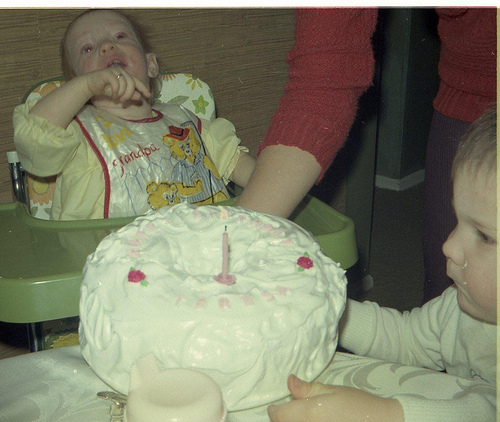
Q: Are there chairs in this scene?
A: Yes, there is a chair.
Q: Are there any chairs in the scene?
A: Yes, there is a chair.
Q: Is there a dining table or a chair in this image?
A: Yes, there is a chair.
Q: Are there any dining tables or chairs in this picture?
A: Yes, there is a chair.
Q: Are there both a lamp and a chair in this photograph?
A: No, there is a chair but no lamps.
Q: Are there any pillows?
A: No, there are no pillows.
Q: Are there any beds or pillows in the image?
A: No, there are no pillows or beds.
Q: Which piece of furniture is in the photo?
A: The piece of furniture is a chair.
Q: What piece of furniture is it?
A: The piece of furniture is a chair.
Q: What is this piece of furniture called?
A: This is a chair.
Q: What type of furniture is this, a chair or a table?
A: This is a chair.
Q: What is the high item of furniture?
A: The piece of furniture is a chair.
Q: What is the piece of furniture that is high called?
A: The piece of furniture is a chair.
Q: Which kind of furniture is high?
A: The furniture is a chair.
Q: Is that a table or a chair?
A: That is a chair.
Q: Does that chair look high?
A: Yes, the chair is high.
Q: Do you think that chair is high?
A: Yes, the chair is high.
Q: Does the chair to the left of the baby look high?
A: Yes, the chair is high.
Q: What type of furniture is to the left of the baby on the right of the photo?
A: The piece of furniture is a chair.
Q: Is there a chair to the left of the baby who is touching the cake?
A: Yes, there is a chair to the left of the baby.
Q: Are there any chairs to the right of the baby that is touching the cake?
A: No, the chair is to the left of the baby.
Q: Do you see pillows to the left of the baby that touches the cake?
A: No, there is a chair to the left of the baby.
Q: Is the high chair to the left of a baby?
A: Yes, the chair is to the left of a baby.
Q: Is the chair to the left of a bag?
A: No, the chair is to the left of a baby.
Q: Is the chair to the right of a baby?
A: No, the chair is to the left of a baby.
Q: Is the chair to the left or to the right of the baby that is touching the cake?
A: The chair is to the left of the baby.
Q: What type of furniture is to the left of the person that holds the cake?
A: The piece of furniture is a chair.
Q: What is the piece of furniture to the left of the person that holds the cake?
A: The piece of furniture is a chair.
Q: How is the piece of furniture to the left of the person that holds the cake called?
A: The piece of furniture is a chair.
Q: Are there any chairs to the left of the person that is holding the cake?
A: Yes, there is a chair to the left of the person.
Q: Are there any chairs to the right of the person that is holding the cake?
A: No, the chair is to the left of the person.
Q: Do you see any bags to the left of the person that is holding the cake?
A: No, there is a chair to the left of the person.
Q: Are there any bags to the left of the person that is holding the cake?
A: No, there is a chair to the left of the person.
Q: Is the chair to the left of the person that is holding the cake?
A: Yes, the chair is to the left of the person.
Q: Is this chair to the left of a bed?
A: No, the chair is to the left of the person.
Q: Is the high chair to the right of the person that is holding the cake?
A: No, the chair is to the left of the person.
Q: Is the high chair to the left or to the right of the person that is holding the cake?
A: The chair is to the left of the person.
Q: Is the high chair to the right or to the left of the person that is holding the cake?
A: The chair is to the left of the person.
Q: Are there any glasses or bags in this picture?
A: No, there are no glasses or bags.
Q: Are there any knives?
A: No, there are no knives.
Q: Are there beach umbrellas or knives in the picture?
A: No, there are no knives or beach umbrellas.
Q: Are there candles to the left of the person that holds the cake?
A: Yes, there is a candle to the left of the person.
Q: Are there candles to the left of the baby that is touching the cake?
A: Yes, there is a candle to the left of the baby.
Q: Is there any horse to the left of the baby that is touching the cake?
A: No, there is a candle to the left of the baby.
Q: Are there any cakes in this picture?
A: Yes, there is a cake.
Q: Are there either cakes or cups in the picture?
A: Yes, there is a cake.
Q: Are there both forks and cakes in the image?
A: No, there is a cake but no forks.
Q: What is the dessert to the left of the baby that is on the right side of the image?
A: The dessert is a cake.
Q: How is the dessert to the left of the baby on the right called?
A: The dessert is a cake.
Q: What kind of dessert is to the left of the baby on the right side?
A: The dessert is a cake.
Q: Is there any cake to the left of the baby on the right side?
A: Yes, there is a cake to the left of the baby.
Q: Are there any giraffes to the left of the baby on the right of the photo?
A: No, there is a cake to the left of the baby.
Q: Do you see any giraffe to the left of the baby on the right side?
A: No, there is a cake to the left of the baby.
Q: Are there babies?
A: Yes, there is a baby.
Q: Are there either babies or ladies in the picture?
A: Yes, there is a baby.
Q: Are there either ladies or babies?
A: Yes, there is a baby.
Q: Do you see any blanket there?
A: No, there are no blankets.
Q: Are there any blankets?
A: No, there are no blankets.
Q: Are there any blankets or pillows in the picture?
A: No, there are no blankets or pillows.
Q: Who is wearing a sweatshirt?
A: The baby is wearing a sweatshirt.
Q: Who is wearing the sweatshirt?
A: The baby is wearing a sweatshirt.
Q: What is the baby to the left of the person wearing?
A: The baby is wearing a sweatshirt.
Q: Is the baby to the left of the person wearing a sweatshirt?
A: Yes, the baby is wearing a sweatshirt.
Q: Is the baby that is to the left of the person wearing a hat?
A: No, the baby is wearing a sweatshirt.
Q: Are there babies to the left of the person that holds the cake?
A: Yes, there is a baby to the left of the person.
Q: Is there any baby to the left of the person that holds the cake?
A: Yes, there is a baby to the left of the person.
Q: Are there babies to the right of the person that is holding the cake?
A: No, the baby is to the left of the person.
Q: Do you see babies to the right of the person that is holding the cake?
A: No, the baby is to the left of the person.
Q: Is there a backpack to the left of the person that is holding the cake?
A: No, there is a baby to the left of the person.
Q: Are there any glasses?
A: No, there are no glasses.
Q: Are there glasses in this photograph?
A: No, there are no glasses.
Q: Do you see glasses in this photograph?
A: No, there are no glasses.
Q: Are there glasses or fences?
A: No, there are no glasses or fences.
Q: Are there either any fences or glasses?
A: No, there are no glasses or fences.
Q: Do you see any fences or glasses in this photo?
A: No, there are no glasses or fences.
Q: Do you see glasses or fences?
A: No, there are no glasses or fences.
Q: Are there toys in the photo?
A: No, there are no toys.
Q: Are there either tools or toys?
A: No, there are no toys or tools.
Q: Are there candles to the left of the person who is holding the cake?
A: Yes, there is a candle to the left of the person.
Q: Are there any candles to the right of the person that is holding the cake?
A: No, the candle is to the left of the person.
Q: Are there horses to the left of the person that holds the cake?
A: No, there is a candle to the left of the person.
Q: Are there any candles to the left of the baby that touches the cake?
A: Yes, there is a candle to the left of the baby.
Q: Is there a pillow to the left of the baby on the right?
A: No, there is a candle to the left of the baby.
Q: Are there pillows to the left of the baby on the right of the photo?
A: No, there is a candle to the left of the baby.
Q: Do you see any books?
A: No, there are no books.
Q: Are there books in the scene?
A: No, there are no books.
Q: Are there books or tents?
A: No, there are no books or tents.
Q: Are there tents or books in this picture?
A: No, there are no books or tents.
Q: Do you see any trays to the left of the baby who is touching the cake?
A: Yes, there is a tray to the left of the baby.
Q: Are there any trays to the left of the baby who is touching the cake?
A: Yes, there is a tray to the left of the baby.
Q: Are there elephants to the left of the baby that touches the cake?
A: No, there is a tray to the left of the baby.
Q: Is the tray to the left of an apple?
A: No, the tray is to the left of a baby.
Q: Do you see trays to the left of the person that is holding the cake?
A: Yes, there is a tray to the left of the person.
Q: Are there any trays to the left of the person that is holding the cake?
A: Yes, there is a tray to the left of the person.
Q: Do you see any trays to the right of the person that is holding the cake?
A: No, the tray is to the left of the person.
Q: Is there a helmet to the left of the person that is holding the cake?
A: No, there is a tray to the left of the person.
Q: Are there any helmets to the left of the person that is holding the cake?
A: No, there is a tray to the left of the person.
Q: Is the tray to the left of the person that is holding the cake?
A: Yes, the tray is to the left of the person.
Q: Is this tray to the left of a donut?
A: No, the tray is to the left of the person.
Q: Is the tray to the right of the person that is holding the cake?
A: No, the tray is to the left of the person.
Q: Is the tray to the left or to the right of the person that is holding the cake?
A: The tray is to the left of the person.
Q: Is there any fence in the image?
A: No, there are no fences.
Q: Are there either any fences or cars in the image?
A: No, there are no fences or cars.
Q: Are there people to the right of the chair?
A: Yes, there is a person to the right of the chair.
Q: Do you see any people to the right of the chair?
A: Yes, there is a person to the right of the chair.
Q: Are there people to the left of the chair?
A: No, the person is to the right of the chair.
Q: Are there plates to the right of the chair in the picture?
A: No, there is a person to the right of the chair.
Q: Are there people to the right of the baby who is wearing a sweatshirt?
A: Yes, there is a person to the right of the baby.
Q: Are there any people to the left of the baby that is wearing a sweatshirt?
A: No, the person is to the right of the baby.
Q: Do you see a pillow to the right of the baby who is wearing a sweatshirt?
A: No, there is a person to the right of the baby.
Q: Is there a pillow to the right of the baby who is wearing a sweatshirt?
A: No, there is a person to the right of the baby.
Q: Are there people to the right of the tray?
A: Yes, there is a person to the right of the tray.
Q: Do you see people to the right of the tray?
A: Yes, there is a person to the right of the tray.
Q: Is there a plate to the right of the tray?
A: No, there is a person to the right of the tray.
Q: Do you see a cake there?
A: Yes, there is a cake.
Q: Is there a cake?
A: Yes, there is a cake.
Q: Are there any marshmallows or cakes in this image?
A: Yes, there is a cake.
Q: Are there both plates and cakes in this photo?
A: No, there is a cake but no plates.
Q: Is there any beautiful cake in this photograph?
A: Yes, there is a beautiful cake.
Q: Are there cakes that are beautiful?
A: Yes, there is a cake that is beautiful.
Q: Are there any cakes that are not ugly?
A: Yes, there is an beautiful cake.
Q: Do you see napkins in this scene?
A: No, there are no napkins.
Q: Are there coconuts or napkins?
A: No, there are no napkins or coconuts.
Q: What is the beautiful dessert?
A: The dessert is a cake.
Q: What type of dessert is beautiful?
A: The dessert is a cake.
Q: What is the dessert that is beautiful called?
A: The dessert is a cake.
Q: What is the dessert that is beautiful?
A: The dessert is a cake.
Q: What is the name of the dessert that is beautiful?
A: The dessert is a cake.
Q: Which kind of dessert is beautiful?
A: The dessert is a cake.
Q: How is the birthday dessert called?
A: The dessert is a cake.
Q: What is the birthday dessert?
A: The dessert is a cake.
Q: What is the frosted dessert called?
A: The dessert is a cake.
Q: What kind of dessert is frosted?
A: The dessert is a cake.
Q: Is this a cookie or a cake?
A: This is a cake.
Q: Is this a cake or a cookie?
A: This is a cake.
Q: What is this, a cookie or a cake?
A: This is a cake.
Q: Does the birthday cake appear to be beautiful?
A: Yes, the cake is beautiful.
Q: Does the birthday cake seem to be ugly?
A: No, the cake is beautiful.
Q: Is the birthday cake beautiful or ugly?
A: The cake is beautiful.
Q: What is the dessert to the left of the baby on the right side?
A: The dessert is a cake.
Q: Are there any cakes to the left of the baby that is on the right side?
A: Yes, there is a cake to the left of the baby.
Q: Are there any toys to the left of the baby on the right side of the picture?
A: No, there is a cake to the left of the baby.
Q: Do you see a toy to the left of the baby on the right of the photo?
A: No, there is a cake to the left of the baby.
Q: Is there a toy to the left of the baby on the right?
A: No, there is a cake to the left of the baby.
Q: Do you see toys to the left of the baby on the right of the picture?
A: No, there is a cake to the left of the baby.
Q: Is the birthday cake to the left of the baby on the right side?
A: Yes, the cake is to the left of the baby.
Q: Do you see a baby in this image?
A: Yes, there is a baby.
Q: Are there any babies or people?
A: Yes, there is a baby.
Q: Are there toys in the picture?
A: No, there are no toys.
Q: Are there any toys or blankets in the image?
A: No, there are no toys or blankets.